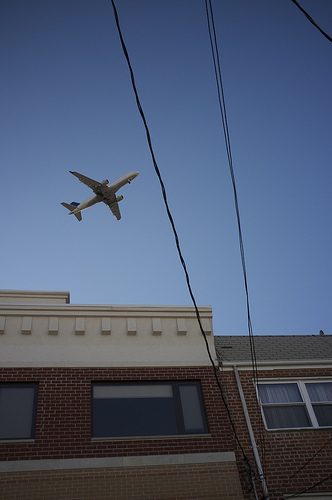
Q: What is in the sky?
A: A plane.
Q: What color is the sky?
A: Blue.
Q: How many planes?
A: One.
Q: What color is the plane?
A: White.